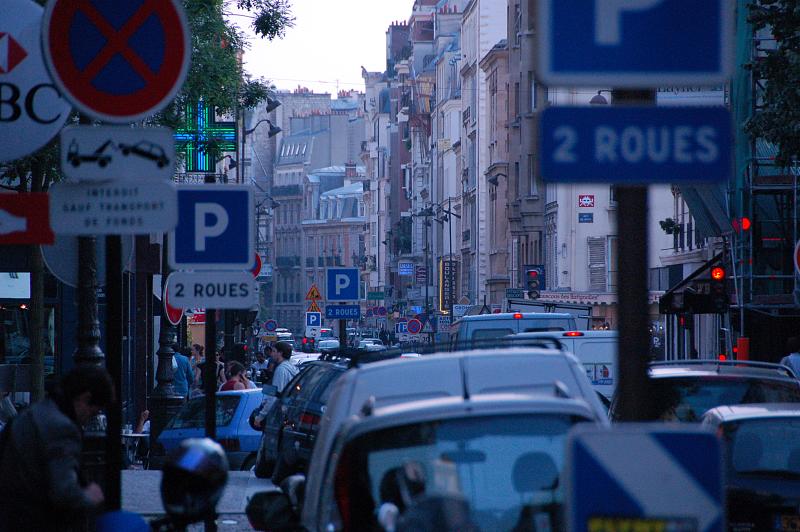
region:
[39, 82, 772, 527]
RUSH HOUR TRAFFIC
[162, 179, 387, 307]
PARKING SIGNS ON THE ROAD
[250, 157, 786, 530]
BUSY AND CONGESTED STREET IN A CITY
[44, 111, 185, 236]
A SIGN SHOWING TOWING ZONE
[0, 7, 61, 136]
PARTIALLY VISIBLE HSBC SIGN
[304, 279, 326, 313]
WARNING SIGNS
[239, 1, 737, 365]
COMMERCIAL AND RESIDENTIAL BUILDINGS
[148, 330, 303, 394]
PEOPLE ON THE STREET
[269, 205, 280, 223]
a window on a building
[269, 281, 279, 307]
a window on a building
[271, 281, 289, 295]
a window on a building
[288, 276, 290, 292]
a window on a building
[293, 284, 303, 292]
a window on a building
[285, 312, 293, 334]
a window on a building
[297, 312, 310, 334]
a window on a building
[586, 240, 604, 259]
a window on a building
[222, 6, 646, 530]
beige and brown buildings along busy street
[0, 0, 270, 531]
group of street signs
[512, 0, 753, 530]
blue sign says 2 roues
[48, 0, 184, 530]
sign shows car being towed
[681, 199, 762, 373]
several red traffic lights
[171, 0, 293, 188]
green foliage near streetlights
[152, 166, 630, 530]
white van near blue and white street sign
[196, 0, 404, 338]
white sky above buildings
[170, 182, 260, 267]
blue sign with a white p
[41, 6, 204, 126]
round blue and red sign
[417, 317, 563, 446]
a vehicle on the road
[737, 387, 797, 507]
a vehicle on the road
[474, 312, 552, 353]
a vehicle on the road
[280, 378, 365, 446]
a vehicle on the road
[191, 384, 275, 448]
a vehicle on the road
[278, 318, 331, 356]
a vehicle on the road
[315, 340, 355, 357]
a vehicle on the road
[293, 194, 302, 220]
glass window on the building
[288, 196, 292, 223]
glass window on the building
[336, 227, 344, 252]
glass window on the building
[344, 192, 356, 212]
glass window on the building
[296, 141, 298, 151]
glass window on the building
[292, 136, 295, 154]
glass window on the building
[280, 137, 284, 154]
glass window on the building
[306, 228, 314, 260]
glass window on the building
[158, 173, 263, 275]
"P" written on a blue sign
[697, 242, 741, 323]
A traffic light is lit red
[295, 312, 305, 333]
A window on a building.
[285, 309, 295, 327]
A window on a building.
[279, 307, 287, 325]
A window on a building.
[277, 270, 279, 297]
A window on a building.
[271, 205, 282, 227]
A window on a building.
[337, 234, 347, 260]
A window on a building.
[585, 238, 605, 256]
A window on a building.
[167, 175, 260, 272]
A white and blue parking sign.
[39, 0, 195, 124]
A red and white traffic sign.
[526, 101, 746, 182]
A blue and white sign.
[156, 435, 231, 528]
A shiny black parking meter.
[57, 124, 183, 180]
A tow away traffic sign.